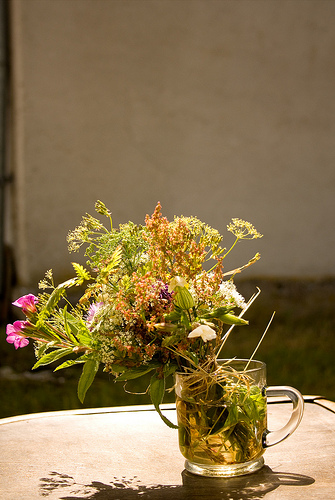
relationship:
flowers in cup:
[20, 193, 299, 397] [174, 359, 303, 478]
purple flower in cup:
[4, 291, 39, 349] [174, 359, 303, 478]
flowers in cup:
[6, 193, 265, 429] [174, 359, 303, 478]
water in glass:
[177, 392, 267, 462] [177, 364, 297, 472]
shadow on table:
[38, 468, 314, 497] [1, 393, 332, 497]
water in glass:
[177, 392, 267, 462] [163, 346, 276, 447]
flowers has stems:
[6, 193, 265, 429] [166, 346, 266, 463]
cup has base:
[171, 355, 306, 476] [182, 458, 267, 478]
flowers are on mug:
[6, 193, 265, 429] [174, 354, 309, 485]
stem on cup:
[195, 395, 270, 449] [174, 359, 303, 478]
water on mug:
[177, 392, 267, 462] [174, 354, 309, 485]